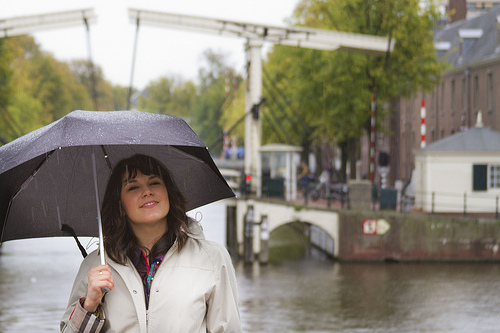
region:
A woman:
[91, 206, 136, 267]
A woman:
[96, 183, 163, 308]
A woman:
[119, 219, 209, 325]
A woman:
[144, 273, 169, 305]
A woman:
[139, 227, 183, 268]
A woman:
[143, 243, 177, 282]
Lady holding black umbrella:
[2, 106, 261, 331]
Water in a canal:
[284, 282, 427, 324]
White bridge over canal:
[262, 204, 338, 264]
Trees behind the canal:
[1, 26, 231, 116]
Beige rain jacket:
[57, 213, 245, 329]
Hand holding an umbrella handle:
[73, 258, 130, 308]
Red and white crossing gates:
[358, 85, 384, 180]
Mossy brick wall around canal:
[411, 220, 466, 256]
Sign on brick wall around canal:
[353, 215, 394, 240]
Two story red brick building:
[432, 3, 494, 123]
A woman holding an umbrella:
[7, 23, 281, 328]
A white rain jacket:
[63, 186, 257, 331]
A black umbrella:
[5, 107, 252, 239]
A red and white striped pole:
[418, 89, 439, 154]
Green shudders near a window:
[464, 151, 499, 197]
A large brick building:
[369, 18, 499, 199]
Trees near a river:
[6, 23, 434, 330]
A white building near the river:
[412, 106, 497, 215]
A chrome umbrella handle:
[84, 149, 111, 317]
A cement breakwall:
[331, 195, 498, 286]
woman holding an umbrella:
[0, 87, 234, 331]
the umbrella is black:
[3, 87, 246, 230]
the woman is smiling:
[96, 167, 201, 277]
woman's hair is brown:
[84, 145, 194, 257]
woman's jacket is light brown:
[65, 239, 244, 329]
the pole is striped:
[407, 83, 435, 139]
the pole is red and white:
[408, 84, 446, 152]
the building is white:
[416, 126, 497, 207]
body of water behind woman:
[12, 231, 495, 331]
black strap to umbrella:
[52, 219, 112, 289]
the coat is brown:
[173, 287, 182, 302]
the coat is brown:
[185, 285, 192, 308]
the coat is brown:
[190, 278, 200, 290]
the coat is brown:
[176, 297, 182, 311]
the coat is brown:
[170, 297, 180, 309]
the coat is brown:
[177, 288, 183, 300]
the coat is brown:
[177, 280, 186, 294]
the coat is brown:
[176, 283, 188, 298]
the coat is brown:
[181, 295, 191, 306]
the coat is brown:
[164, 275, 178, 302]